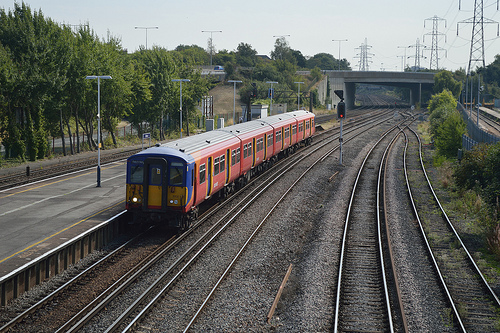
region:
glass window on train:
[197, 164, 207, 183]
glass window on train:
[212, 157, 220, 174]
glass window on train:
[219, 154, 226, 171]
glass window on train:
[230, 149, 236, 164]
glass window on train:
[235, 147, 241, 161]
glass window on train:
[242, 143, 248, 157]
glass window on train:
[245, 141, 252, 157]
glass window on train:
[255, 138, 260, 150]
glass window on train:
[258, 136, 264, 151]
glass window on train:
[275, 130, 280, 141]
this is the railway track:
[208, 237, 241, 257]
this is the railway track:
[407, 130, 418, 175]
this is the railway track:
[425, 195, 445, 255]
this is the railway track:
[392, 260, 437, 315]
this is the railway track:
[335, 250, 375, 325]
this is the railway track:
[70, 245, 106, 330]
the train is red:
[195, 135, 230, 186]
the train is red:
[242, 123, 278, 169]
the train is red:
[290, 115, 305, 140]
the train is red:
[254, 109, 299, 171]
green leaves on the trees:
[6, 22, 70, 131]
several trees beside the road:
[4, 22, 184, 121]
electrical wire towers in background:
[422, 11, 453, 68]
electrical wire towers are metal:
[416, 9, 449, 68]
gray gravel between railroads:
[247, 230, 267, 315]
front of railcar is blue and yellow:
[125, 154, 197, 213]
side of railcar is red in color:
[191, 148, 250, 190]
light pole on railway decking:
[78, 72, 119, 191]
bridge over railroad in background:
[328, 67, 441, 107]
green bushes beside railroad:
[425, 120, 462, 155]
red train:
[118, 103, 323, 211]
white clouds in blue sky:
[121, 5, 191, 52]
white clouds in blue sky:
[360, 9, 402, 39]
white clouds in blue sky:
[414, 13, 461, 53]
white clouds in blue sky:
[342, 11, 389, 53]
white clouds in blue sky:
[279, 3, 343, 66]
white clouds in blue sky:
[249, 11, 289, 42]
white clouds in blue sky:
[182, 10, 246, 44]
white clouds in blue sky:
[114, 9, 163, 40]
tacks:
[189, 253, 316, 299]